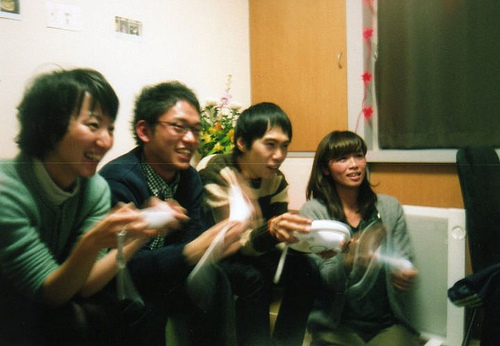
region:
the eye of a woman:
[84, 117, 101, 130]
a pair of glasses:
[145, 115, 205, 137]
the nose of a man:
[178, 127, 196, 144]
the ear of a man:
[134, 117, 151, 144]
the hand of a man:
[271, 207, 313, 245]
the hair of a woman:
[305, 126, 378, 224]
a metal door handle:
[331, 49, 346, 69]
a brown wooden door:
[248, 0, 350, 155]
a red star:
[359, 70, 374, 84]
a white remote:
[109, 196, 179, 309]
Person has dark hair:
[36, 50, 102, 158]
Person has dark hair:
[143, 82, 235, 161]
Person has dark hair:
[230, 109, 315, 171]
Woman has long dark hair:
[316, 130, 430, 285]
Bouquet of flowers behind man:
[206, 69, 268, 182]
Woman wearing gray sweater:
[303, 183, 401, 304]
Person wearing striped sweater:
[207, 140, 269, 266]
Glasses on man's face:
[159, 111, 202, 155]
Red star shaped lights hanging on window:
[336, 20, 391, 152]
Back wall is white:
[36, 22, 170, 82]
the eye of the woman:
[86, 120, 101, 132]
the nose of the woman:
[92, 125, 114, 150]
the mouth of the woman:
[81, 148, 105, 163]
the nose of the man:
[181, 127, 196, 143]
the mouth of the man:
[171, 143, 194, 160]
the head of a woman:
[12, 63, 120, 180]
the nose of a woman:
[94, 125, 114, 152]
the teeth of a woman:
[84, 150, 104, 161]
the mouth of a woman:
[84, 149, 105, 164]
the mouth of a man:
[174, 142, 193, 158]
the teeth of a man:
[176, 145, 193, 154]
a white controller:
[112, 195, 178, 310]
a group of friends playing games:
[3, 58, 421, 338]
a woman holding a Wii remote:
[4, 59, 179, 326]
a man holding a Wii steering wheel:
[209, 102, 346, 337]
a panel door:
[247, 0, 353, 159]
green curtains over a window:
[372, 0, 497, 150]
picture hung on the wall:
[0, 0, 153, 50]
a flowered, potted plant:
[186, 60, 249, 163]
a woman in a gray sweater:
[297, 190, 417, 330]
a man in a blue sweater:
[107, 146, 229, 303]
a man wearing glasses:
[135, 106, 206, 153]